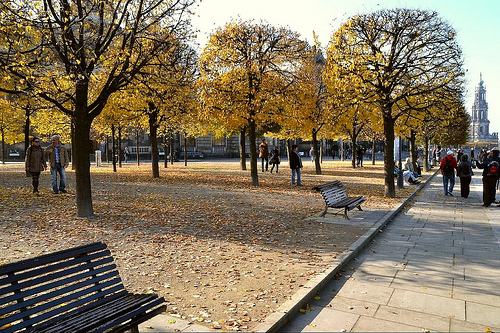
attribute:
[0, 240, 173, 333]
bench — painted, black, wooden, brown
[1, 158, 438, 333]
leaf — yellow, brown, covered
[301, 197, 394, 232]
base — concrete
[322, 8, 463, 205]
leaf — yellow, tall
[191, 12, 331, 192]
leaf — yellow, tall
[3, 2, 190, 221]
tree — tall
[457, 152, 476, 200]
person — walking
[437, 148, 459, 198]
person — walking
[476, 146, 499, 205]
person — walking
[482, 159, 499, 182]
backpack — black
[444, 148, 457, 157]
hat — white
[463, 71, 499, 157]
building — tall, white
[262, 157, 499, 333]
street — concrete, stone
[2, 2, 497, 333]
park — small, public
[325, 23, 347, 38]
leaf — colored, yellow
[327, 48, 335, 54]
leaf — colored, gold, yellow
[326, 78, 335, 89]
leaf — colored, gold, yellow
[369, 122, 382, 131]
leaf — colored, gold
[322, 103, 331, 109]
leaf — colored, gold, yellow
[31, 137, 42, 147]
sunglasses — black, dark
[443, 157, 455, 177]
backpack — black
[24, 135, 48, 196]
woman — walking, wife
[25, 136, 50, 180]
jacket — brown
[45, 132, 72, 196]
man — walking, husband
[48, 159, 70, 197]
pants — blue, jean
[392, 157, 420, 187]
person — sitting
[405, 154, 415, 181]
person — sitting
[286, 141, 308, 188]
person — walking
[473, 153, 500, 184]
jacket — black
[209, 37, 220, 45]
leaf — yellow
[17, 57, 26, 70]
leaf — yellow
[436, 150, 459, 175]
shirt — red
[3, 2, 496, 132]
sky — white, blue, bright